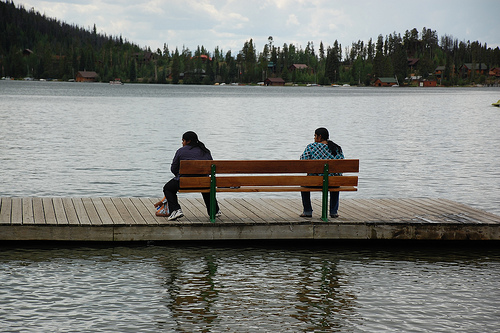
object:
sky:
[0, 0, 500, 62]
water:
[0, 79, 500, 333]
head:
[182, 131, 198, 147]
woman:
[163, 131, 221, 222]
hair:
[315, 127, 343, 157]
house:
[76, 70, 98, 82]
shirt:
[299, 140, 346, 176]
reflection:
[157, 250, 216, 333]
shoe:
[166, 208, 185, 221]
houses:
[372, 78, 397, 85]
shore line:
[0, 77, 500, 90]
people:
[296, 128, 343, 216]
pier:
[0, 196, 500, 240]